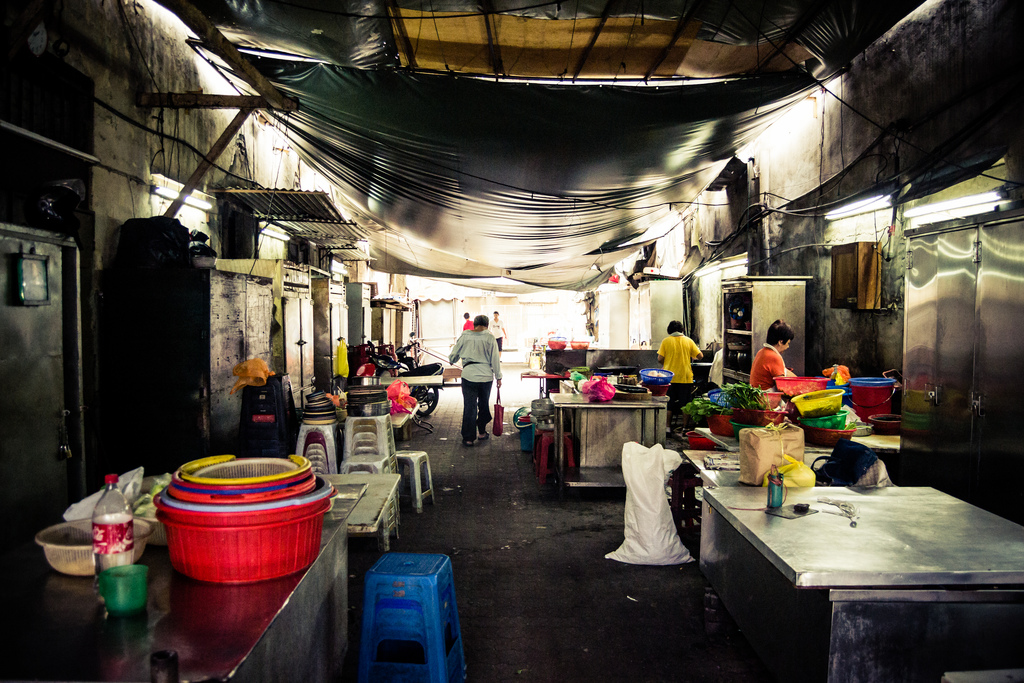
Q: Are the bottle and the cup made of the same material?
A: Yes, both the bottle and the cup are made of plastic.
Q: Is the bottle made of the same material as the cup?
A: Yes, both the bottle and the cup are made of plastic.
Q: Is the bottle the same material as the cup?
A: Yes, both the bottle and the cup are made of plastic.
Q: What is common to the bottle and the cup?
A: The material, both the bottle and the cup are plastic.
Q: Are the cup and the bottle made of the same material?
A: Yes, both the cup and the bottle are made of plastic.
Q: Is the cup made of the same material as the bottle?
A: Yes, both the cup and the bottle are made of plastic.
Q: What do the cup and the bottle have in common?
A: The material, both the cup and the bottle are plastic.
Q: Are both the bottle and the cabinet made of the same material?
A: No, the bottle is made of plastic and the cabinet is made of wood.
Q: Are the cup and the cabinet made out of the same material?
A: No, the cup is made of plastic and the cabinet is made of wood.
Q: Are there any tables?
A: Yes, there is a table.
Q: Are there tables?
A: Yes, there is a table.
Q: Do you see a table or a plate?
A: Yes, there is a table.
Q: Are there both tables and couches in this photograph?
A: No, there is a table but no couches.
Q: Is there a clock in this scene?
A: No, there are no clocks.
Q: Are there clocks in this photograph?
A: No, there are no clocks.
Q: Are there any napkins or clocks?
A: No, there are no clocks or napkins.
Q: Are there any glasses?
A: No, there are no glasses.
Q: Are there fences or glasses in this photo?
A: No, there are no glasses or fences.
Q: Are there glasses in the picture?
A: No, there are no glasses.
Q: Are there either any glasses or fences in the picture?
A: No, there are no glasses or fences.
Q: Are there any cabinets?
A: Yes, there is a cabinet.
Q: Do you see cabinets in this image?
A: Yes, there is a cabinet.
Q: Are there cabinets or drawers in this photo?
A: Yes, there is a cabinet.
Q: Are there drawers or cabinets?
A: Yes, there is a cabinet.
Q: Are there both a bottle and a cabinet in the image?
A: Yes, there are both a cabinet and a bottle.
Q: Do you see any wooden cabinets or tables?
A: Yes, there is a wood cabinet.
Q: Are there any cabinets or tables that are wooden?
A: Yes, the cabinet is wooden.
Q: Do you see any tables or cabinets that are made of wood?
A: Yes, the cabinet is made of wood.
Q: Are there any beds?
A: No, there are no beds.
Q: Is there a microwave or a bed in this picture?
A: No, there are no beds or microwaves.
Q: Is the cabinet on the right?
A: Yes, the cabinet is on the right of the image.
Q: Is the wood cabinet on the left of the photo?
A: No, the cabinet is on the right of the image.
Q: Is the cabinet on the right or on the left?
A: The cabinet is on the right of the image.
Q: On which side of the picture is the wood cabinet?
A: The cabinet is on the right of the image.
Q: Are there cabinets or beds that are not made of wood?
A: No, there is a cabinet but it is made of wood.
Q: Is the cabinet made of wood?
A: Yes, the cabinet is made of wood.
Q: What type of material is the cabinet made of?
A: The cabinet is made of wood.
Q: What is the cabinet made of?
A: The cabinet is made of wood.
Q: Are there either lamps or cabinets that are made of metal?
A: No, there is a cabinet but it is made of wood.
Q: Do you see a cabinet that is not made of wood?
A: No, there is a cabinet but it is made of wood.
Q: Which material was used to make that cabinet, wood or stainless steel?
A: The cabinet is made of wood.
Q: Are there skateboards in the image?
A: No, there are no skateboards.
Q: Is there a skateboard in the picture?
A: No, there are no skateboards.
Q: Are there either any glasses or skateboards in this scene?
A: No, there are no skateboards or glasses.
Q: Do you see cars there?
A: No, there are no cars.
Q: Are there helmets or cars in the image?
A: No, there are no cars or helmets.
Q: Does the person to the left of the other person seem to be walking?
A: Yes, the person is walking.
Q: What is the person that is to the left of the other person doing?
A: The person is walking.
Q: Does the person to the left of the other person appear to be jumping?
A: No, the person is walking.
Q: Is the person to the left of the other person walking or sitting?
A: The person is walking.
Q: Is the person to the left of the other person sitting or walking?
A: The person is walking.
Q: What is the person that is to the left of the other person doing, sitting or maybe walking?
A: The person is walking.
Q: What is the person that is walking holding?
A: The person is holding the bag.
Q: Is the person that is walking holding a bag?
A: Yes, the person is holding a bag.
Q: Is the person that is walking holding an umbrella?
A: No, the person is holding a bag.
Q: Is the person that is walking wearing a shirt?
A: Yes, the person is wearing a shirt.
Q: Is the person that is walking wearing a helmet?
A: No, the person is wearing a shirt.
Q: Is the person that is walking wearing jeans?
A: Yes, the person is wearing jeans.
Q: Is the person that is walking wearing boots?
A: No, the person is wearing jeans.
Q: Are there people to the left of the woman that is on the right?
A: Yes, there is a person to the left of the woman.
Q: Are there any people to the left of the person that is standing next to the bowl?
A: Yes, there is a person to the left of the woman.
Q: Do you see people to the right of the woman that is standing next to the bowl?
A: No, the person is to the left of the woman.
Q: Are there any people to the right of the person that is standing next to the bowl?
A: No, the person is to the left of the woman.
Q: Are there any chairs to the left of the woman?
A: No, there is a person to the left of the woman.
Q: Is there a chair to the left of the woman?
A: No, there is a person to the left of the woman.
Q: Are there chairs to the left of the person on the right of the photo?
A: No, there is a person to the left of the woman.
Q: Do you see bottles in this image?
A: Yes, there is a bottle.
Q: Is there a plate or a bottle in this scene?
A: Yes, there is a bottle.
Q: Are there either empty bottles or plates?
A: Yes, there is an empty bottle.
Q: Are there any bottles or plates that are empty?
A: Yes, the bottle is empty.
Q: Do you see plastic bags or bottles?
A: Yes, there is a plastic bottle.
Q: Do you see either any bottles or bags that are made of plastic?
A: Yes, the bottle is made of plastic.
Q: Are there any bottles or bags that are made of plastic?
A: Yes, the bottle is made of plastic.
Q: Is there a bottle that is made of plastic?
A: Yes, there is a bottle that is made of plastic.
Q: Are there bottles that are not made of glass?
A: Yes, there is a bottle that is made of plastic.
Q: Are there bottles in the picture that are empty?
A: Yes, there is an empty bottle.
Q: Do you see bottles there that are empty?
A: Yes, there is a bottle that is empty.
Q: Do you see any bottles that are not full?
A: Yes, there is a empty bottle.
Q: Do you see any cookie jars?
A: No, there are no cookie jars.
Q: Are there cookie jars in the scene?
A: No, there are no cookie jars.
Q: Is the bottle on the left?
A: Yes, the bottle is on the left of the image.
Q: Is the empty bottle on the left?
A: Yes, the bottle is on the left of the image.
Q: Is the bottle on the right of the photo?
A: No, the bottle is on the left of the image.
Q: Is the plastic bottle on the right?
A: No, the bottle is on the left of the image.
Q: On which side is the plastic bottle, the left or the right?
A: The bottle is on the left of the image.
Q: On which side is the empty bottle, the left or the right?
A: The bottle is on the left of the image.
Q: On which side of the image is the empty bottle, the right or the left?
A: The bottle is on the left of the image.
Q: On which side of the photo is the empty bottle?
A: The bottle is on the left of the image.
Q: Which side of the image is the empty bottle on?
A: The bottle is on the left of the image.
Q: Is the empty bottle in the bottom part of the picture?
A: Yes, the bottle is in the bottom of the image.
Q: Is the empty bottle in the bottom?
A: Yes, the bottle is in the bottom of the image.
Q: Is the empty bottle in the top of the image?
A: No, the bottle is in the bottom of the image.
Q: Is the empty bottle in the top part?
A: No, the bottle is in the bottom of the image.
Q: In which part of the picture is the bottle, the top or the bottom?
A: The bottle is in the bottom of the image.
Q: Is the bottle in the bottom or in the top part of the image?
A: The bottle is in the bottom of the image.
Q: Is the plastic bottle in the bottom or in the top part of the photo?
A: The bottle is in the bottom of the image.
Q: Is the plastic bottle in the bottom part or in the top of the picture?
A: The bottle is in the bottom of the image.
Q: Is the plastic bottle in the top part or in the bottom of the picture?
A: The bottle is in the bottom of the image.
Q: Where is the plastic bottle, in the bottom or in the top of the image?
A: The bottle is in the bottom of the image.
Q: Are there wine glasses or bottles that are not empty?
A: No, there is a bottle but it is empty.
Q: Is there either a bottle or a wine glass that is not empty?
A: No, there is a bottle but it is empty.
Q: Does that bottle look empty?
A: Yes, the bottle is empty.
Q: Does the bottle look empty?
A: Yes, the bottle is empty.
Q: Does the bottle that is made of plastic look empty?
A: Yes, the bottle is empty.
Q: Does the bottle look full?
A: No, the bottle is empty.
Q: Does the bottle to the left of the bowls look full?
A: No, the bottle is empty.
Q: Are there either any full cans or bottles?
A: No, there is a bottle but it is empty.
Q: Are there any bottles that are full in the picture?
A: No, there is a bottle but it is empty.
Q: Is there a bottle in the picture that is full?
A: No, there is a bottle but it is empty.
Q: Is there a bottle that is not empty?
A: No, there is a bottle but it is empty.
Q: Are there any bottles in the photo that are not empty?
A: No, there is a bottle but it is empty.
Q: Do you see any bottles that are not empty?
A: No, there is a bottle but it is empty.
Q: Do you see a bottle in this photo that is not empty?
A: No, there is a bottle but it is empty.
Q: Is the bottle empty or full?
A: The bottle is empty.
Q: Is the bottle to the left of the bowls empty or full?
A: The bottle is empty.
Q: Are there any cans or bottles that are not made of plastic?
A: No, there is a bottle but it is made of plastic.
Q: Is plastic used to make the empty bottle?
A: Yes, the bottle is made of plastic.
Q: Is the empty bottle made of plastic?
A: Yes, the bottle is made of plastic.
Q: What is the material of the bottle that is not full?
A: The bottle is made of plastic.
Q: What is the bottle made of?
A: The bottle is made of plastic.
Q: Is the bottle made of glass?
A: No, the bottle is made of plastic.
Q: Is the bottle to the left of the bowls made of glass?
A: No, the bottle is made of plastic.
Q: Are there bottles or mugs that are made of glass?
A: No, there is a bottle but it is made of plastic.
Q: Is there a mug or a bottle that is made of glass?
A: No, there is a bottle but it is made of plastic.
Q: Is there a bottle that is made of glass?
A: No, there is a bottle but it is made of plastic.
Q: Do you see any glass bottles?
A: No, there is a bottle but it is made of plastic.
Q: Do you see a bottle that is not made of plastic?
A: No, there is a bottle but it is made of plastic.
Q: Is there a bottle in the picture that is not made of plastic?
A: No, there is a bottle but it is made of plastic.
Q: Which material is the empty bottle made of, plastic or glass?
A: The bottle is made of plastic.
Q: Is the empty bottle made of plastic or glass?
A: The bottle is made of plastic.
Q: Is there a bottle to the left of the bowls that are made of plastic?
A: Yes, there is a bottle to the left of the bowls.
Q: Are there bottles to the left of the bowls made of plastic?
A: Yes, there is a bottle to the left of the bowls.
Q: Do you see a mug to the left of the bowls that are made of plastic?
A: No, there is a bottle to the left of the bowls.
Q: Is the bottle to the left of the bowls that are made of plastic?
A: Yes, the bottle is to the left of the bowls.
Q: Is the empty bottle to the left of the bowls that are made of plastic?
A: Yes, the bottle is to the left of the bowls.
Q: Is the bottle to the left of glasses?
A: No, the bottle is to the left of the bowls.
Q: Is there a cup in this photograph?
A: Yes, there is a cup.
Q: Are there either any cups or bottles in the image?
A: Yes, there is a cup.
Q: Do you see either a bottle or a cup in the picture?
A: Yes, there is a cup.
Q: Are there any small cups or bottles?
A: Yes, there is a small cup.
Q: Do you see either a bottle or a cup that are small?
A: Yes, the cup is small.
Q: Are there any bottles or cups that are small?
A: Yes, the cup is small.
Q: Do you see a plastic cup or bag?
A: Yes, there is a plastic cup.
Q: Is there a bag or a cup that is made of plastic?
A: Yes, the cup is made of plastic.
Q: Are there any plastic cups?
A: Yes, there is a cup that is made of plastic.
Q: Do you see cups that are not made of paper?
A: Yes, there is a cup that is made of plastic.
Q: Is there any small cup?
A: Yes, there is a small cup.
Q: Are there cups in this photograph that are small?
A: Yes, there is a cup that is small.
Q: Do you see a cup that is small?
A: Yes, there is a cup that is small.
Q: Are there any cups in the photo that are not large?
A: Yes, there is a small cup.